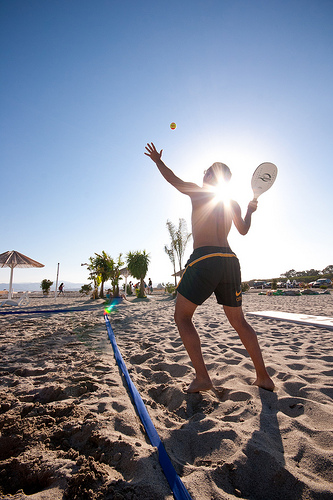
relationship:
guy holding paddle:
[143, 141, 277, 392] [251, 162, 278, 201]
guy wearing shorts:
[143, 141, 277, 392] [174, 245, 244, 307]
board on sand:
[249, 301, 332, 330] [1, 290, 332, 499]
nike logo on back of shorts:
[231, 286, 245, 302] [167, 246, 269, 334]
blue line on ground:
[104, 311, 190, 499] [4, 287, 327, 497]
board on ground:
[249, 301, 332, 340] [4, 287, 327, 497]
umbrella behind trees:
[88, 253, 150, 299] [86, 248, 151, 299]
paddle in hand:
[247, 158, 280, 217] [248, 195, 264, 211]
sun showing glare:
[186, 140, 251, 213] [207, 178, 239, 207]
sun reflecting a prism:
[186, 140, 251, 213] [103, 296, 119, 317]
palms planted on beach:
[127, 250, 151, 297] [0, 281, 331, 499]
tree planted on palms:
[109, 249, 122, 296] [127, 250, 151, 297]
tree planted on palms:
[95, 247, 113, 295] [127, 250, 151, 297]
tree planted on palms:
[83, 255, 100, 299] [127, 250, 151, 297]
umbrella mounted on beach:
[2, 230, 58, 308] [10, 318, 62, 466]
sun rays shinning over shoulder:
[180, 160, 245, 227] [224, 193, 242, 212]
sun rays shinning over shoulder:
[180, 160, 245, 227] [181, 182, 203, 199]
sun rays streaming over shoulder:
[180, 160, 245, 227] [224, 193, 242, 212]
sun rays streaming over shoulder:
[180, 160, 245, 227] [181, 182, 203, 199]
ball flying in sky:
[170, 121, 177, 130] [0, 0, 332, 287]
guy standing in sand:
[143, 141, 277, 392] [1, 305, 174, 498]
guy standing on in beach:
[143, 141, 277, 392] [194, 405, 321, 497]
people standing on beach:
[57, 282, 66, 297] [26, 292, 72, 355]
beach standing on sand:
[26, 292, 72, 355] [33, 299, 105, 498]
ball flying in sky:
[167, 121, 176, 130] [0, 1, 320, 139]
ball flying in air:
[170, 121, 177, 130] [1, 2, 327, 273]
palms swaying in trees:
[87, 248, 149, 301] [239, 263, 331, 288]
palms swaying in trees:
[162, 216, 189, 268] [239, 263, 331, 288]